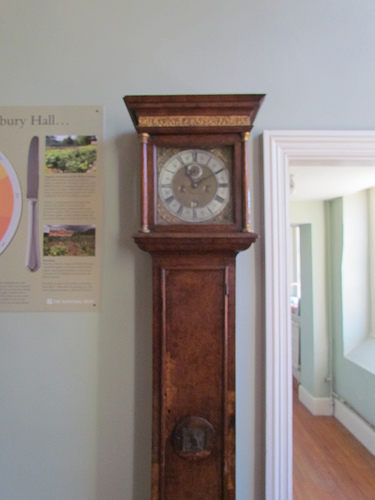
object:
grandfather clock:
[121, 93, 265, 499]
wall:
[0, 0, 262, 499]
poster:
[0, 104, 102, 312]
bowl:
[0, 149, 23, 258]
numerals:
[161, 151, 229, 223]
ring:
[157, 147, 231, 222]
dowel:
[139, 132, 150, 233]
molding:
[262, 129, 293, 423]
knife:
[25, 135, 40, 272]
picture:
[42, 133, 99, 260]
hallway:
[289, 168, 375, 500]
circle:
[187, 161, 202, 179]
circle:
[171, 161, 217, 208]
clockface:
[156, 145, 234, 224]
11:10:
[177, 155, 225, 188]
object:
[172, 416, 215, 463]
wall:
[324, 182, 375, 459]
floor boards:
[292, 373, 375, 500]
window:
[340, 188, 374, 377]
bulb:
[291, 166, 364, 201]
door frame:
[260, 127, 374, 498]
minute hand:
[182, 165, 194, 183]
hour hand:
[197, 169, 222, 183]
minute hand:
[197, 167, 227, 185]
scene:
[0, 0, 372, 499]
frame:
[122, 93, 267, 252]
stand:
[134, 232, 258, 499]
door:
[261, 129, 374, 498]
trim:
[139, 115, 251, 127]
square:
[186, 161, 226, 190]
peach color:
[0, 163, 14, 242]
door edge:
[261, 128, 375, 163]